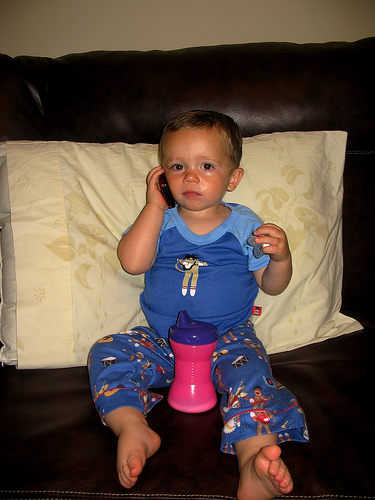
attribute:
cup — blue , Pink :
[163, 306, 225, 416]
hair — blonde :
[151, 104, 243, 170]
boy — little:
[87, 120, 291, 498]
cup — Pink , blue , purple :
[168, 309, 218, 413]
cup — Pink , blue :
[159, 315, 235, 406]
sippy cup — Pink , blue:
[166, 311, 223, 417]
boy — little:
[153, 114, 224, 228]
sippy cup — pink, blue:
[158, 306, 224, 413]